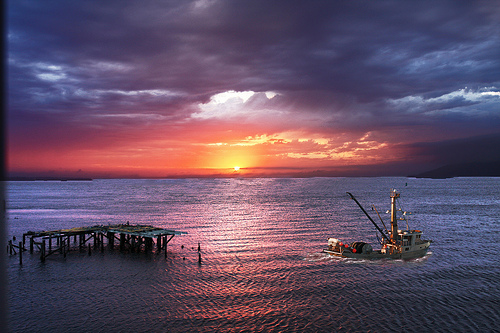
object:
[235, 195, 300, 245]
water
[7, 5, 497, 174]
sky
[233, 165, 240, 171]
sun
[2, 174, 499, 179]
horizon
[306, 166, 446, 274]
large boat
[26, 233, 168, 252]
support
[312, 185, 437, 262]
boat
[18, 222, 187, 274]
wooden pier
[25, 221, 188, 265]
platform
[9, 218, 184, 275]
pier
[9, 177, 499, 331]
water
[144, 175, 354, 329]
reflection